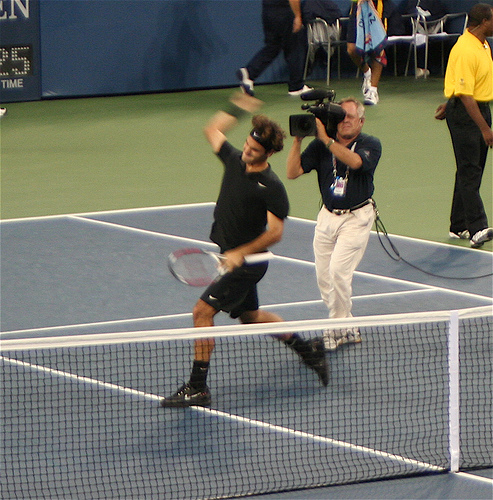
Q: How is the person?
A: In motion.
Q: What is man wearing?
A: Black clothing.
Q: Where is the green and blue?
A: The court.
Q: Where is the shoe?
A: On foot.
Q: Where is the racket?
A: In hand.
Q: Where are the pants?
A: On man.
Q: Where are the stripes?
A: On court.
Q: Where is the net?
A: On court.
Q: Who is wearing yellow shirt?
A: A man.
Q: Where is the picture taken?
A: A tennis court.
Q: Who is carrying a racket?
A: Federer.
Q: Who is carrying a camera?
A: The cameraman.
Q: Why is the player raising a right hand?
A: He won.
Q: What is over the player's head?
A: Sweatband.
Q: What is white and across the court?
A: A net.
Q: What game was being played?
A: Tennis.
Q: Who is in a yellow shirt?
A: An umpire.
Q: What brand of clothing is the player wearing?
A: Nike.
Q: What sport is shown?
A: Tennis.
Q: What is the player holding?
A: Tennis racquet.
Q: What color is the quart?
A: Blue.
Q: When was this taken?
A: Daytime.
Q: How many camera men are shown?
A: 1.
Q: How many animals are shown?
A: 0.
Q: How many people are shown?
A: 5.